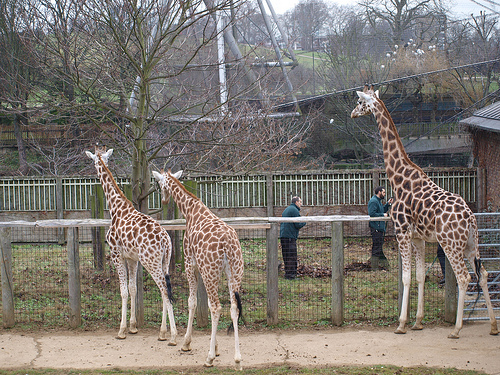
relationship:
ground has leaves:
[248, 238, 400, 291] [303, 262, 327, 276]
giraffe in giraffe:
[348, 85, 499, 338] [348, 85, 499, 338]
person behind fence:
[280, 195, 309, 278] [240, 207, 405, 313]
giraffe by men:
[348, 85, 499, 338] [280, 187, 389, 277]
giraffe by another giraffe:
[348, 85, 499, 338] [83, 142, 177, 348]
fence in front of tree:
[240, 207, 405, 313] [2, 1, 329, 261]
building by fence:
[458, 96, 498, 256] [240, 207, 405, 313]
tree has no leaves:
[2, 1, 329, 261] [178, 66, 294, 173]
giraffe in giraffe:
[83, 142, 177, 348] [348, 85, 499, 338]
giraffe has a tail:
[348, 85, 499, 338] [464, 210, 486, 301]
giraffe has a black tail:
[348, 85, 499, 338] [469, 216, 481, 299]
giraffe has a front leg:
[348, 85, 499, 338] [391, 212, 411, 334]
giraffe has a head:
[348, 85, 499, 338] [350, 83, 382, 119]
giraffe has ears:
[348, 85, 499, 338] [355, 87, 381, 99]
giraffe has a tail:
[83, 142, 177, 348] [161, 267, 176, 302]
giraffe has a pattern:
[348, 85, 499, 338] [398, 189, 444, 232]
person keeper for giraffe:
[280, 195, 309, 278] [348, 85, 499, 338]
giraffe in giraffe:
[153, 168, 245, 372] [348, 85, 499, 338]